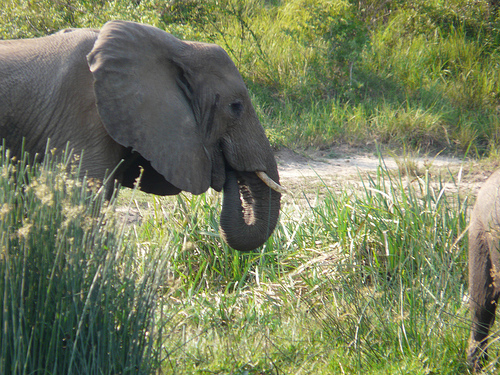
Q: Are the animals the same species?
A: Yes, all the animals are elephants.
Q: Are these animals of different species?
A: No, all the animals are elephants.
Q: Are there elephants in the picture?
A: Yes, there is an elephant.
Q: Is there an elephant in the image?
A: Yes, there is an elephant.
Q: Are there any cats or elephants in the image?
A: Yes, there is an elephant.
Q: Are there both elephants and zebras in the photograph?
A: No, there is an elephant but no zebras.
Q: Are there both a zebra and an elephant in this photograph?
A: No, there is an elephant but no zebras.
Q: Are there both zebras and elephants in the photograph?
A: No, there is an elephant but no zebras.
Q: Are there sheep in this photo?
A: No, there are no sheep.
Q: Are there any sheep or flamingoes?
A: No, there are no sheep or flamingoes.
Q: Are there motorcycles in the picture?
A: No, there are no motorcycles.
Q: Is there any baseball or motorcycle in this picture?
A: No, there are no motorcycles or baseballs.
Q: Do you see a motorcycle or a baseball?
A: No, there are no motorcycles or baseballs.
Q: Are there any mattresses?
A: No, there are no mattresses.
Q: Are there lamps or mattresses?
A: No, there are no mattresses or lamps.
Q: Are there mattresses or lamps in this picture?
A: No, there are no mattresses or lamps.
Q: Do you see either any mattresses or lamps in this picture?
A: No, there are no mattresses or lamps.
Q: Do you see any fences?
A: No, there are no fences.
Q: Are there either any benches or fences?
A: No, there are no fences or benches.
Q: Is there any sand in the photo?
A: Yes, there is sand.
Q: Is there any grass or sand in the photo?
A: Yes, there is sand.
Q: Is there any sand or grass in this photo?
A: Yes, there is sand.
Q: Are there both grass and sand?
A: Yes, there are both sand and grass.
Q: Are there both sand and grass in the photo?
A: Yes, there are both sand and grass.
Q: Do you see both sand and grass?
A: Yes, there are both sand and grass.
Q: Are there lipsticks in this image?
A: No, there are no lipsticks.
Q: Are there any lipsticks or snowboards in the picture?
A: No, there are no lipsticks or snowboards.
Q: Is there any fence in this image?
A: No, there are no fences.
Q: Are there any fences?
A: No, there are no fences.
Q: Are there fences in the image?
A: No, there are no fences.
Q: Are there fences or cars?
A: No, there are no fences or cars.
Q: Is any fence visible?
A: No, there are no fences.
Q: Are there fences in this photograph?
A: No, there are no fences.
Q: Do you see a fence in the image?
A: No, there are no fences.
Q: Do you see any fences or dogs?
A: No, there are no fences or dogs.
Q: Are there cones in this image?
A: No, there are no cones.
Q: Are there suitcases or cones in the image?
A: No, there are no cones or suitcases.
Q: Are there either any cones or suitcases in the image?
A: No, there are no cones or suitcases.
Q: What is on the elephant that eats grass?
A: The trunk is on the elephant.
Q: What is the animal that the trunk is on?
A: The animal is an elephant.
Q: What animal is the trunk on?
A: The trunk is on the elephant.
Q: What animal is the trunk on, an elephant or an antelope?
A: The trunk is on an elephant.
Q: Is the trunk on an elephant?
A: Yes, the trunk is on an elephant.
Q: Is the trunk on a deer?
A: No, the trunk is on an elephant.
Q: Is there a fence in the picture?
A: No, there are no fences.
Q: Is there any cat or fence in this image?
A: No, there are no fences or cats.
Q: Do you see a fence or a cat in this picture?
A: No, there are no fences or cats.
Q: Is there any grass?
A: Yes, there is grass.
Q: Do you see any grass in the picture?
A: Yes, there is grass.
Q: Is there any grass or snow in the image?
A: Yes, there is grass.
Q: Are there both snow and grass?
A: No, there is grass but no snow.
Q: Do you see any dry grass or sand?
A: Yes, there is dry grass.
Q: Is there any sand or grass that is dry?
A: Yes, the grass is dry.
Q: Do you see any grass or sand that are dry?
A: Yes, the grass is dry.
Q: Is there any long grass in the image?
A: Yes, there is long grass.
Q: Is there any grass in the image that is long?
A: Yes, there is grass that is long.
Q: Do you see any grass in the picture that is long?
A: Yes, there is grass that is long.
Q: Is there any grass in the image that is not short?
A: Yes, there is long grass.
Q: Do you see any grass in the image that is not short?
A: Yes, there is long grass.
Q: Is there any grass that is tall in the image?
A: Yes, there is tall grass.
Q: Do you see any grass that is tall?
A: Yes, there is grass that is tall.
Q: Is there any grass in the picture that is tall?
A: Yes, there is grass that is tall.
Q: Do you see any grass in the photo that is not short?
A: Yes, there is tall grass.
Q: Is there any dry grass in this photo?
A: Yes, there is dry grass.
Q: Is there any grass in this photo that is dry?
A: Yes, there is grass that is dry.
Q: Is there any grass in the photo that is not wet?
A: Yes, there is dry grass.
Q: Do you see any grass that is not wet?
A: Yes, there is dry grass.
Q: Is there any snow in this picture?
A: No, there is no snow.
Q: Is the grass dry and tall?
A: Yes, the grass is dry and tall.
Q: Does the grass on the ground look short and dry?
A: No, the grass is dry but tall.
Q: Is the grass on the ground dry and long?
A: Yes, the grass is dry and long.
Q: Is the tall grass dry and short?
A: No, the grass is dry but long.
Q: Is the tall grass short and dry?
A: No, the grass is dry but long.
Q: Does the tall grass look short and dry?
A: No, the grass is dry but long.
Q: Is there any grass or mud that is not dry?
A: No, there is grass but it is dry.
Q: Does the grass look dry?
A: Yes, the grass is dry.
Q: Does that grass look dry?
A: Yes, the grass is dry.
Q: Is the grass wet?
A: No, the grass is dry.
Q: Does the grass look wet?
A: No, the grass is dry.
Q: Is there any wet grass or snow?
A: No, there is grass but it is dry.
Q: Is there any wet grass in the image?
A: No, there is grass but it is dry.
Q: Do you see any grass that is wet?
A: No, there is grass but it is dry.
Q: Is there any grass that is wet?
A: No, there is grass but it is dry.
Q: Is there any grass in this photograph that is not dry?
A: No, there is grass but it is dry.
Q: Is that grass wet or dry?
A: The grass is dry.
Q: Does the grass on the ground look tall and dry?
A: Yes, the grass is tall and dry.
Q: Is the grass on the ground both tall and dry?
A: Yes, the grass is tall and dry.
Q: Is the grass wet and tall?
A: No, the grass is tall but dry.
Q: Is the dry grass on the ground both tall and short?
A: No, the grass is tall but long.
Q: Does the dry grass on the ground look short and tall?
A: No, the grass is tall but long.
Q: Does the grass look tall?
A: Yes, the grass is tall.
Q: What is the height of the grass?
A: The grass is tall.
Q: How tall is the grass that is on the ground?
A: The grass is tall.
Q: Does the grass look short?
A: No, the grass is tall.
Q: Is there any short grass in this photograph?
A: No, there is grass but it is tall.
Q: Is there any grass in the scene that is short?
A: No, there is grass but it is tall.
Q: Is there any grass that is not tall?
A: No, there is grass but it is tall.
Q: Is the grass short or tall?
A: The grass is tall.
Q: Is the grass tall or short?
A: The grass is tall.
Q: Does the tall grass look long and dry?
A: Yes, the grass is long and dry.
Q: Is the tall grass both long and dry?
A: Yes, the grass is long and dry.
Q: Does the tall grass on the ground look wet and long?
A: No, the grass is long but dry.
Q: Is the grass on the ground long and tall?
A: Yes, the grass is long and tall.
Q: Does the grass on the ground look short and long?
A: No, the grass is long but tall.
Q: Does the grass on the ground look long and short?
A: No, the grass is long but tall.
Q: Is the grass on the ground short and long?
A: No, the grass is long but tall.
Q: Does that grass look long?
A: Yes, the grass is long.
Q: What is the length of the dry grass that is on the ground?
A: The grass is long.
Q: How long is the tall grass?
A: The grass is long.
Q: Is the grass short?
A: No, the grass is long.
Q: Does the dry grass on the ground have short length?
A: No, the grass is long.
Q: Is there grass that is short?
A: No, there is grass but it is long.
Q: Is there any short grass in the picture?
A: No, there is grass but it is long.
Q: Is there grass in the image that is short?
A: No, there is grass but it is long.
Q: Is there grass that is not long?
A: No, there is grass but it is long.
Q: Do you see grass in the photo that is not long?
A: No, there is grass but it is long.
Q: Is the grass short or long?
A: The grass is long.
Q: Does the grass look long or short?
A: The grass is long.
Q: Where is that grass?
A: The grass is on the ground.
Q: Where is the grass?
A: The grass is on the ground.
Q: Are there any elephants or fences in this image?
A: Yes, there is an elephant.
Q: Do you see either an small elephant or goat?
A: Yes, there is a small elephant.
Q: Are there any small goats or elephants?
A: Yes, there is a small elephant.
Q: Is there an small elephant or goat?
A: Yes, there is a small elephant.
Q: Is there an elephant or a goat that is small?
A: Yes, the elephant is small.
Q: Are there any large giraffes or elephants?
A: Yes, there is a large elephant.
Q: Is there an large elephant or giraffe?
A: Yes, there is a large elephant.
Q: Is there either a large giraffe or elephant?
A: Yes, there is a large elephant.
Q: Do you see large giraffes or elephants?
A: Yes, there is a large elephant.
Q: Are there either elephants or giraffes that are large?
A: Yes, the elephant is large.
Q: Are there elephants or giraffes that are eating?
A: Yes, the elephant is eating.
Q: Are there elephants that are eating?
A: Yes, there is an elephant that is eating.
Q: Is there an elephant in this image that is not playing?
A: Yes, there is an elephant that is eating.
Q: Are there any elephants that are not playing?
A: Yes, there is an elephant that is eating.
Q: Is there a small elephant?
A: Yes, there is a small elephant.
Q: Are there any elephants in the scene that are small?
A: Yes, there is a small elephant.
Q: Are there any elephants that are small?
A: Yes, there is an elephant that is small.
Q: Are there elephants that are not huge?
A: Yes, there is a small elephant.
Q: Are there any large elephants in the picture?
A: Yes, there is a large elephant.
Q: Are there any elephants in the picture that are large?
A: Yes, there is an elephant that is large.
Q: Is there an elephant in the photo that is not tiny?
A: Yes, there is a large elephant.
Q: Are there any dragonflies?
A: No, there are no dragonflies.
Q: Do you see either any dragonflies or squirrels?
A: No, there are no dragonflies or squirrels.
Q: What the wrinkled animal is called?
A: The animal is an elephant.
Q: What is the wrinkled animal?
A: The animal is an elephant.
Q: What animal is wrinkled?
A: The animal is an elephant.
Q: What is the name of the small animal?
A: The animal is an elephant.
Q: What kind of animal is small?
A: The animal is an elephant.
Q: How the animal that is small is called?
A: The animal is an elephant.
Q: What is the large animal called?
A: The animal is an elephant.